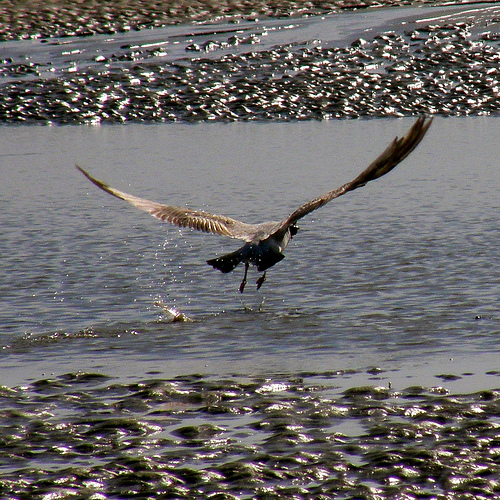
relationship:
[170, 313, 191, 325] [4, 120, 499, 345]
fish in water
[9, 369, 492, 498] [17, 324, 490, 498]
seaweed near shore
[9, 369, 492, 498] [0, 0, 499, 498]
seaweed has ground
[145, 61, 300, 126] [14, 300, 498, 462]
rocks in water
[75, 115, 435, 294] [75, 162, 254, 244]
bird has outstretched wing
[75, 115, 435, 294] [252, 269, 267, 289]
bird has foot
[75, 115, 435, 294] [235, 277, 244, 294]
bird has foot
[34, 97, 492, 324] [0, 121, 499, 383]
bird flying over water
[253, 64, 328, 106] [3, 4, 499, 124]
wet rocks along shore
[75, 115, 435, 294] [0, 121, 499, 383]
bird in water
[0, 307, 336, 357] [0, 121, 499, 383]
ripples in water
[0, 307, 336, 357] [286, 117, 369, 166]
ripples in water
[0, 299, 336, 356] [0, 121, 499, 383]
ripples in water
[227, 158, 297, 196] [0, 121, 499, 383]
ripples in water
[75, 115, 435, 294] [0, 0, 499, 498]
bird low to ground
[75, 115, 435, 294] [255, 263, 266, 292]
bird has foot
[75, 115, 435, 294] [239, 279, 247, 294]
bird has feet